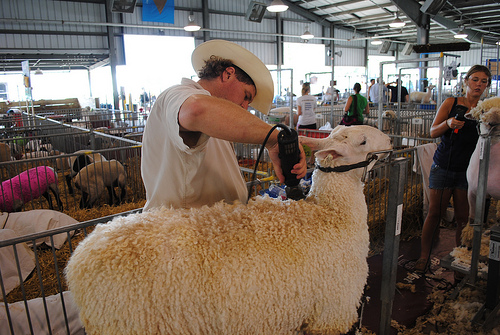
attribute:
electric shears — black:
[246, 124, 303, 200]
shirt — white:
[139, 78, 248, 214]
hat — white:
[191, 38, 274, 115]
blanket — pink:
[2, 165, 57, 211]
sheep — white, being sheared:
[1, 165, 64, 213]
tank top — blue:
[432, 97, 484, 170]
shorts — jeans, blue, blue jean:
[430, 160, 469, 189]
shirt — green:
[348, 94, 368, 122]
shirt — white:
[298, 94, 317, 126]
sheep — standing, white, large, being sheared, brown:
[64, 123, 394, 334]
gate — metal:
[94, 131, 146, 200]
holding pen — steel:
[1, 129, 148, 215]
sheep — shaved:
[460, 97, 499, 251]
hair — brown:
[198, 54, 256, 84]